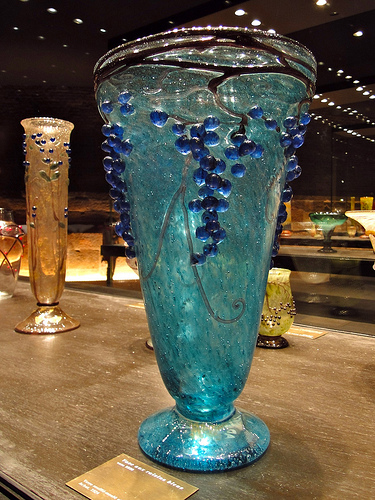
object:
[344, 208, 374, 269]
martini glass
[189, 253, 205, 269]
dot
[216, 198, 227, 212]
dot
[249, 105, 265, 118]
dot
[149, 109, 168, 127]
dot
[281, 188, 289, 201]
dot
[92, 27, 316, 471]
cup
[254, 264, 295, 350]
glass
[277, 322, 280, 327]
beads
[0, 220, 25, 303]
clear glass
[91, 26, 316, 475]
vase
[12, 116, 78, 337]
vase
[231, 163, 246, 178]
blue stones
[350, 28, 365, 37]
ceiling light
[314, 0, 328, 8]
ceiling light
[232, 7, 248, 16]
ceiling light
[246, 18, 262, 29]
ceiling light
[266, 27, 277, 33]
ceiling light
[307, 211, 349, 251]
vase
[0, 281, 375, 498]
table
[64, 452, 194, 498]
place card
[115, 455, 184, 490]
lettering